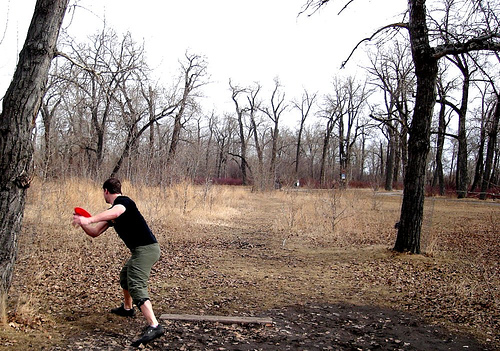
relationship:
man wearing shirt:
[72, 179, 163, 345] [110, 197, 156, 250]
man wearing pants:
[72, 179, 163, 345] [118, 242, 161, 297]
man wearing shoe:
[72, 179, 163, 345] [110, 304, 131, 316]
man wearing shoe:
[72, 179, 163, 345] [140, 325, 163, 340]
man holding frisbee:
[72, 179, 163, 345] [74, 207, 88, 219]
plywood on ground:
[159, 313, 272, 327] [0, 183, 495, 344]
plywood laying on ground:
[159, 313, 272, 327] [0, 183, 495, 344]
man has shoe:
[72, 179, 163, 345] [110, 304, 131, 316]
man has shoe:
[72, 179, 163, 345] [140, 325, 163, 340]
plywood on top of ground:
[159, 313, 272, 327] [0, 183, 495, 344]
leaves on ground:
[42, 250, 117, 304] [0, 183, 495, 344]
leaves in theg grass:
[42, 250, 117, 304] [28, 174, 192, 224]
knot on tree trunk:
[29, 37, 45, 53] [0, 1, 67, 275]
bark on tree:
[410, 142, 419, 165] [299, 2, 497, 253]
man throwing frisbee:
[72, 179, 163, 345] [74, 207, 88, 219]